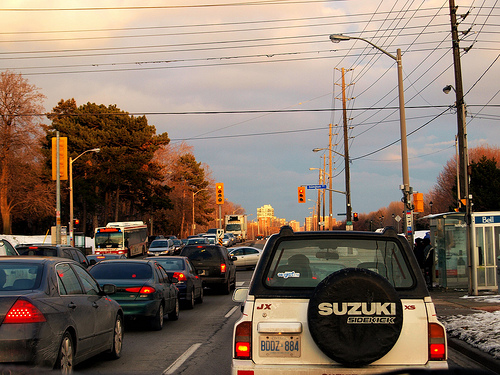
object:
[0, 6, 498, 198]
sky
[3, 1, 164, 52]
clouds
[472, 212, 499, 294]
stop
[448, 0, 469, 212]
pole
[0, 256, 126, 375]
cars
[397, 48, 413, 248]
poles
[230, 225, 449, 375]
rear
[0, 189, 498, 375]
traffic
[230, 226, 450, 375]
back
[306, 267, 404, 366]
black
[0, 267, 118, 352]
blue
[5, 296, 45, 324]
lit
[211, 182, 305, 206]
two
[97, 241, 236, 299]
stop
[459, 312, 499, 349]
snow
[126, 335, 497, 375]
sidewalk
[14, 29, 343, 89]
ominous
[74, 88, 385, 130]
storm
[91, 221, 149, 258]
bus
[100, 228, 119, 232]
top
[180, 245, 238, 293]
suv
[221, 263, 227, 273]
light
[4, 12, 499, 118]
electrical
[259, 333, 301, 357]
license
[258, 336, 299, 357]
numbers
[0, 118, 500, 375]
view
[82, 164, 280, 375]
street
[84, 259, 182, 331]
car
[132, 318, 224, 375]
ashphalt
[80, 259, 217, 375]
road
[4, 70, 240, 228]
trees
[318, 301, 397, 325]
suzuki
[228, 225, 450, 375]
car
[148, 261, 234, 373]
middle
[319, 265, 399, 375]
tire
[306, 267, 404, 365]
tire